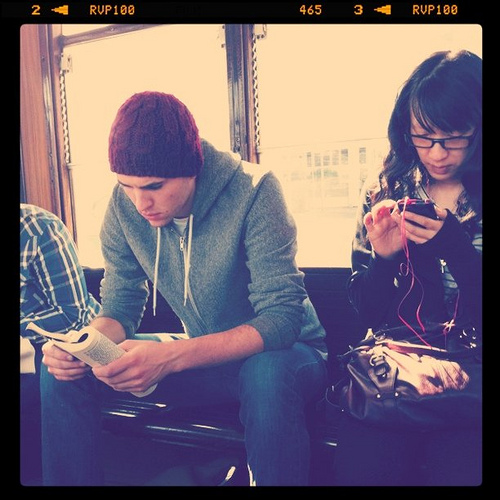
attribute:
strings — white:
[153, 213, 193, 316]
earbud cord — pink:
[400, 197, 460, 349]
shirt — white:
[95, 137, 330, 349]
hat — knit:
[94, 97, 204, 168]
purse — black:
[328, 325, 478, 430]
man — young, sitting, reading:
[38, 89, 330, 484]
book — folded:
[21, 298, 161, 398]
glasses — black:
[405, 125, 477, 150]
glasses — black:
[393, 127, 476, 157]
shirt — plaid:
[12, 196, 109, 371]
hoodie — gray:
[46, 97, 377, 374]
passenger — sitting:
[310, 47, 485, 498]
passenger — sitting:
[36, 90, 333, 484]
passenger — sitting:
[19, 202, 106, 485]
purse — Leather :
[348, 325, 475, 437]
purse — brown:
[325, 313, 481, 430]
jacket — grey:
[96, 146, 314, 351]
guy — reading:
[105, 92, 293, 372]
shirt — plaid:
[17, 204, 99, 345]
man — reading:
[38, 111, 342, 453]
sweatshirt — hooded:
[99, 141, 326, 346]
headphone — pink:
[400, 192, 419, 207]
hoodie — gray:
[82, 134, 338, 356]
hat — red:
[102, 85, 206, 179]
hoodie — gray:
[94, 138, 328, 351]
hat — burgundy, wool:
[108, 91, 205, 177]